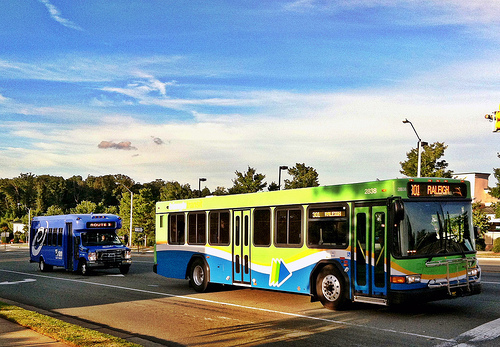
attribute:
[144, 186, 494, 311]
bus — green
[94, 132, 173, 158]
clouds — dark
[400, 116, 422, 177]
street lamp — metal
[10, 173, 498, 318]
bus — blue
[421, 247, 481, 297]
bike — metal 